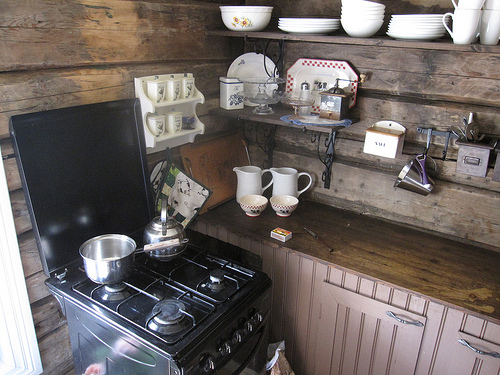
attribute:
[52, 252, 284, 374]
stove — black, new, gas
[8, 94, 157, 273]
lid — open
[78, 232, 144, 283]
pan — silver, stainless steel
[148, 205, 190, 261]
kettle — silver, metal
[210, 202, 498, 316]
counter — wood, wooden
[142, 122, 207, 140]
shelf — white, hanging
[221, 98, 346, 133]
shelf — wooden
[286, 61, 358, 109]
plate — red, white, decorative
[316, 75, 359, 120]
coffee grinder — manual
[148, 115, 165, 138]
pot — white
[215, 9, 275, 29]
bowl — white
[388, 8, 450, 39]
plates — white, stacked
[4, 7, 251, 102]
logs — wooden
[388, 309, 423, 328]
handle — silver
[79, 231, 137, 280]
pot — silver, metal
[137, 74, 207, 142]
rack — white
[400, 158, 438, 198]
cup — silver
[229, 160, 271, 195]
pitcher — white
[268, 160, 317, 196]
pitcher — white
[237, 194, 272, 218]
bowl — colorful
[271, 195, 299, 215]
bowl — colorful